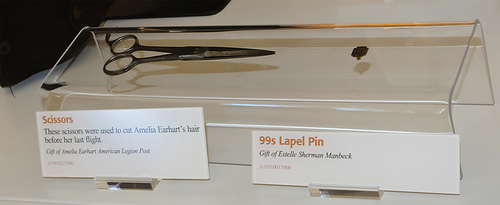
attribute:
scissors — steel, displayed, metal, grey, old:
[103, 30, 276, 76]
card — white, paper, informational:
[35, 106, 209, 179]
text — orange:
[43, 115, 73, 123]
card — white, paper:
[252, 131, 461, 195]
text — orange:
[280, 135, 305, 146]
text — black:
[43, 127, 61, 134]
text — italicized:
[139, 148, 150, 154]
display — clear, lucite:
[39, 19, 496, 179]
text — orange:
[308, 136, 324, 147]